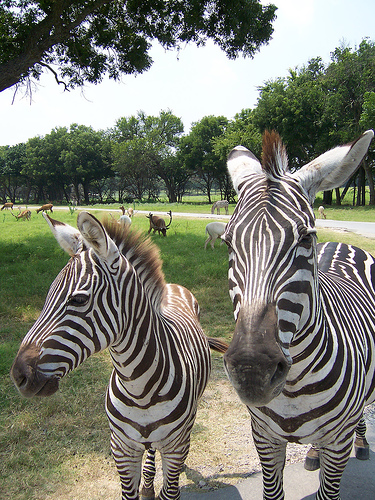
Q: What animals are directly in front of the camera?
A: Zebras.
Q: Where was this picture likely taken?
A: A zoo.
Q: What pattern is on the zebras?
A: Stripes.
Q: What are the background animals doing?
A: Grazing.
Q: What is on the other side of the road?
A: Trees.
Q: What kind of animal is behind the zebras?
A: Reindeer.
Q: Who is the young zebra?
A: On the left.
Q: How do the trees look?
A: Green.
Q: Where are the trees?
A: Behind animals.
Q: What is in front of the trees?
A: Road.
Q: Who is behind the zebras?
A: Deer.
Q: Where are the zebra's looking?
A: Forward.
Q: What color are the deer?
A: Brown and white.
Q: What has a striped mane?
A: The zebra.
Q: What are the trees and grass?
A: Green.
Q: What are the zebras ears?
A: Sticking up.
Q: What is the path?
A: Through the grass.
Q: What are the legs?
A: The zebra.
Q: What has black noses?
A: The zebras.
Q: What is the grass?
A: Tall.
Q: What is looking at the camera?
A: The zebra.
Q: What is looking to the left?
A: The young zebra.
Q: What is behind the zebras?
A: More animals.